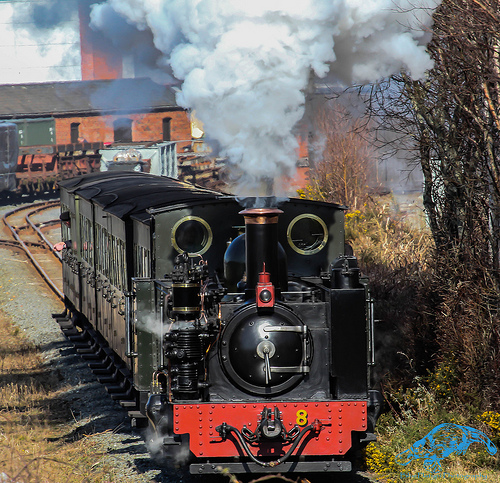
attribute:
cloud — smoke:
[0, 0, 497, 210]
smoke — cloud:
[195, 35, 266, 116]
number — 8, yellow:
[291, 406, 313, 431]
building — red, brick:
[0, 77, 190, 197]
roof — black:
[1, 78, 191, 120]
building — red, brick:
[0, 76, 193, 173]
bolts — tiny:
[172, 400, 215, 420]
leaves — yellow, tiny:
[365, 442, 399, 478]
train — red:
[58, 173, 382, 481]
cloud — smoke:
[169, 15, 335, 168]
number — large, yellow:
[294, 403, 309, 436]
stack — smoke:
[239, 205, 286, 297]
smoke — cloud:
[208, 8, 306, 90]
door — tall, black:
[111, 116, 133, 141]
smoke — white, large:
[79, 3, 389, 211]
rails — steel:
[5, 218, 65, 287]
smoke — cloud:
[112, 3, 432, 202]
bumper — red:
[170, 396, 371, 467]